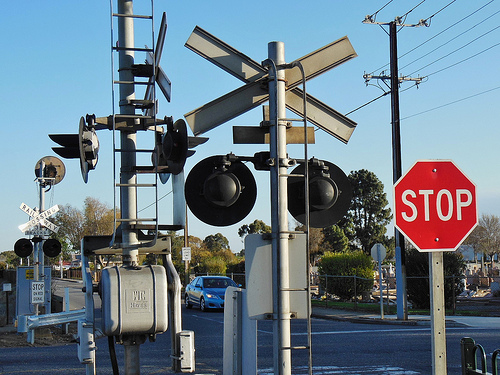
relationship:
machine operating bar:
[100, 262, 170, 342] [115, 3, 141, 264]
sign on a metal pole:
[393, 157, 481, 252] [426, 247, 463, 373]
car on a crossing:
[182, 274, 242, 311] [77, 30, 498, 370]